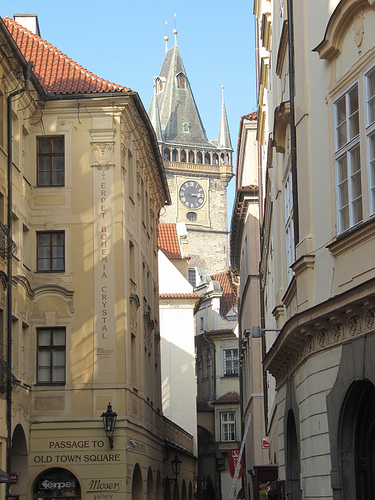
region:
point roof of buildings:
[134, 13, 243, 134]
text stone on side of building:
[90, 178, 124, 356]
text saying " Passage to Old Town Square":
[38, 433, 150, 469]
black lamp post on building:
[84, 399, 118, 425]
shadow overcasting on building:
[149, 301, 217, 445]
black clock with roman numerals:
[170, 173, 241, 229]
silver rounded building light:
[234, 321, 279, 351]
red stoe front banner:
[227, 442, 280, 498]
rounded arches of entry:
[14, 410, 184, 498]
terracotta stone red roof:
[36, 42, 78, 91]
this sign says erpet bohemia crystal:
[80, 142, 133, 362]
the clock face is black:
[170, 177, 223, 218]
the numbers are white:
[169, 166, 223, 218]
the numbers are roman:
[173, 169, 229, 250]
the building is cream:
[274, 19, 350, 110]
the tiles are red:
[37, 32, 129, 137]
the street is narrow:
[116, 91, 323, 323]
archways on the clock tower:
[129, 136, 180, 211]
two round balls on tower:
[141, 23, 208, 84]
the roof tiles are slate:
[130, 26, 220, 119]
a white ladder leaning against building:
[218, 409, 263, 497]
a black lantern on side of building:
[98, 386, 120, 450]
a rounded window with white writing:
[25, 460, 88, 495]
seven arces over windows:
[131, 469, 198, 494]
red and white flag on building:
[215, 442, 246, 497]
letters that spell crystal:
[90, 284, 114, 340]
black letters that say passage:
[32, 436, 89, 448]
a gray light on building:
[222, 316, 284, 354]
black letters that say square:
[78, 449, 129, 468]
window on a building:
[204, 397, 251, 446]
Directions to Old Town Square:
[19, 423, 130, 492]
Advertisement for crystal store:
[88, 131, 120, 412]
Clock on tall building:
[172, 159, 221, 244]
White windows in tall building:
[255, 60, 369, 377]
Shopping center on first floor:
[13, 409, 238, 499]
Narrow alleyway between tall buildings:
[141, 183, 282, 492]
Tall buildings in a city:
[199, 92, 374, 491]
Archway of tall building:
[252, 372, 372, 481]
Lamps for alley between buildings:
[96, 403, 200, 483]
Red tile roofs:
[148, 217, 201, 301]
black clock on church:
[175, 178, 216, 211]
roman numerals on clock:
[184, 175, 207, 211]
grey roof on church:
[153, 52, 206, 138]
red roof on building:
[13, 22, 116, 98]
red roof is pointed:
[1, 13, 101, 89]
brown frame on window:
[29, 132, 74, 199]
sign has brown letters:
[28, 434, 114, 472]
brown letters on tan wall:
[33, 427, 125, 489]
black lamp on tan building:
[97, 399, 131, 457]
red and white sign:
[216, 443, 247, 487]